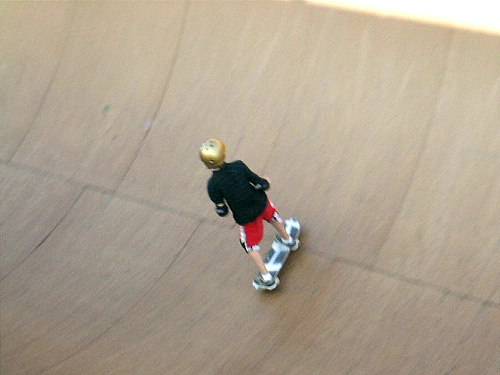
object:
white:
[264, 277, 271, 279]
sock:
[262, 273, 271, 281]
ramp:
[2, 2, 313, 104]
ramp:
[196, 1, 444, 84]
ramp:
[189, 285, 361, 372]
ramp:
[304, 309, 494, 372]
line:
[329, 255, 496, 318]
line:
[73, 182, 203, 242]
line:
[3, 182, 86, 280]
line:
[110, 12, 198, 197]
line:
[7, 0, 68, 167]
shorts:
[238, 199, 281, 251]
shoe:
[253, 275, 278, 289]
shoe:
[273, 233, 299, 252]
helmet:
[197, 137, 230, 168]